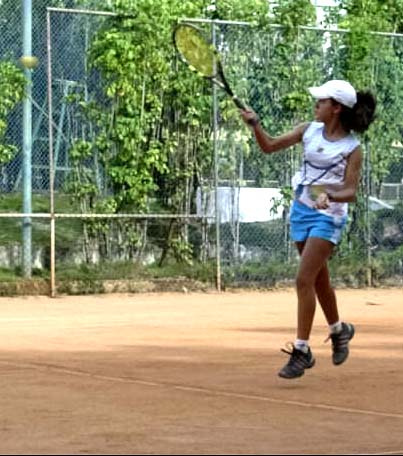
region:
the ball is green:
[22, 48, 45, 75]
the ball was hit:
[19, 43, 38, 66]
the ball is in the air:
[20, 46, 38, 68]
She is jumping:
[265, 313, 371, 410]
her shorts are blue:
[276, 213, 351, 243]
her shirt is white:
[290, 102, 353, 217]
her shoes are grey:
[255, 319, 358, 396]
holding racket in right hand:
[134, 18, 288, 134]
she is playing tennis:
[97, 47, 376, 337]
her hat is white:
[306, 62, 366, 108]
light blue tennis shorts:
[289, 201, 344, 244]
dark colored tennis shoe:
[279, 353, 316, 377]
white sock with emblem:
[293, 338, 310, 351]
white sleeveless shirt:
[305, 122, 348, 209]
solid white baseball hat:
[307, 77, 357, 104]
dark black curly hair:
[355, 90, 377, 127]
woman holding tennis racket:
[176, 23, 263, 147]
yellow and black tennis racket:
[167, 24, 243, 104]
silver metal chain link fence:
[242, 226, 274, 242]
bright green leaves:
[0, 59, 20, 123]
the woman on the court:
[164, 15, 387, 374]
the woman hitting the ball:
[164, 7, 378, 399]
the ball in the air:
[10, 53, 43, 73]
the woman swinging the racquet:
[160, 10, 401, 399]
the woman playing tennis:
[160, 15, 363, 389]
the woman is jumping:
[163, 14, 377, 381]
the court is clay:
[8, 301, 401, 450]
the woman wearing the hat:
[292, 71, 355, 111]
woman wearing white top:
[286, 118, 365, 222]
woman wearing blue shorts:
[265, 197, 354, 250]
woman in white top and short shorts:
[156, 7, 389, 386]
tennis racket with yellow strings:
[156, 12, 270, 151]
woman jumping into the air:
[217, 70, 370, 390]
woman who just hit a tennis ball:
[225, 72, 383, 388]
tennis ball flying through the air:
[14, 49, 43, 76]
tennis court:
[3, 281, 400, 454]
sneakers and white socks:
[271, 315, 361, 388]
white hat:
[297, 70, 363, 115]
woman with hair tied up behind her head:
[229, 70, 386, 396]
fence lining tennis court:
[0, 1, 402, 285]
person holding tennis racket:
[167, 16, 389, 383]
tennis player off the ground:
[171, 12, 369, 390]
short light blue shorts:
[280, 188, 357, 250]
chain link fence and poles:
[34, 4, 171, 288]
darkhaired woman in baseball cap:
[296, 69, 380, 136]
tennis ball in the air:
[11, 43, 43, 81]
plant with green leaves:
[77, 4, 179, 260]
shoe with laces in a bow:
[270, 341, 318, 378]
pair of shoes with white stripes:
[280, 317, 361, 382]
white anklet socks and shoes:
[271, 314, 358, 387]